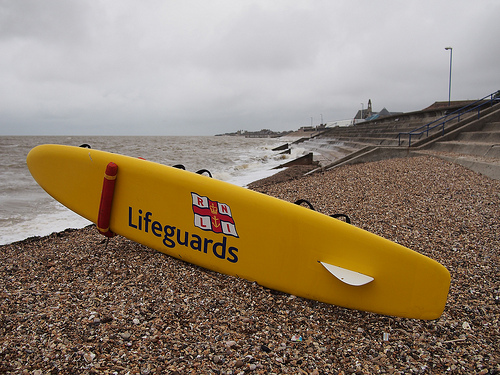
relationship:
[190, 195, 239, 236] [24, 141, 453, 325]
flag on board is visible